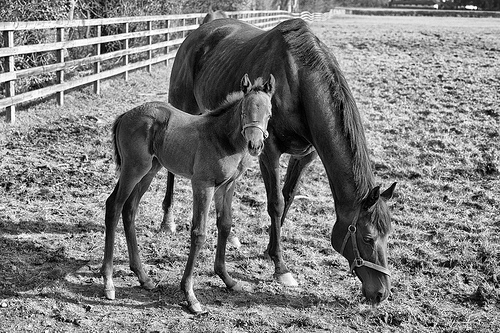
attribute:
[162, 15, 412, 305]
horse — dark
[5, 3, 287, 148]
fencing — wooden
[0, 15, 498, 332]
grass — sparse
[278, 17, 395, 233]
mane — dark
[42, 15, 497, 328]
area — fenced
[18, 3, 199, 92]
fence — wooden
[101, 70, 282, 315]
colt — light colored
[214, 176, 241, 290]
leg — long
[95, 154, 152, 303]
leg — long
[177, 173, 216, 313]
leg — long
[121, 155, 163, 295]
leg — long